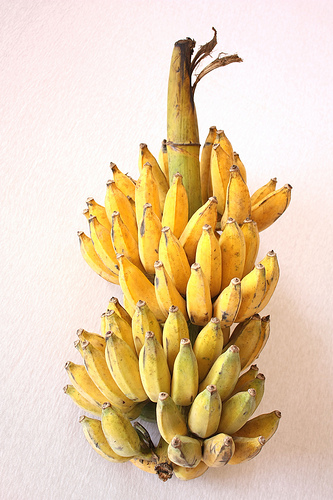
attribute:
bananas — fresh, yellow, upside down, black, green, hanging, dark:
[64, 125, 292, 483]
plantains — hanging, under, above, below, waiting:
[63, 119, 295, 484]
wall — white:
[2, 2, 332, 496]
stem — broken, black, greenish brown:
[164, 38, 203, 220]